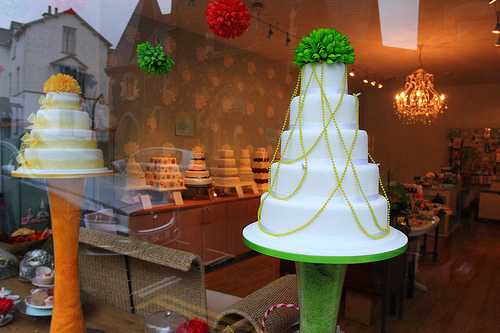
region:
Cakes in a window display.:
[5, 3, 448, 329]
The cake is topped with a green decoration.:
[261, 20, 381, 265]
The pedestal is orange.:
[10, 170, 125, 320]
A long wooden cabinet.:
[115, 195, 265, 275]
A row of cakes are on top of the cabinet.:
[105, 125, 276, 230]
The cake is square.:
[135, 150, 182, 201]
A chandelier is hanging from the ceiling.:
[380, 36, 452, 141]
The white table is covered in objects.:
[385, 160, 445, 296]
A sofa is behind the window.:
[0, 180, 305, 330]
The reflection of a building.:
[0, 6, 116, 166]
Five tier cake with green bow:
[257, 18, 425, 276]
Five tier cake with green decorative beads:
[267, 6, 403, 266]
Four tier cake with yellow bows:
[10, 53, 114, 178]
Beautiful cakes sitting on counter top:
[117, 133, 283, 214]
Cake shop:
[13, 10, 498, 332]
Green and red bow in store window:
[134, 1, 253, 79]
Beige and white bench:
[87, 226, 303, 331]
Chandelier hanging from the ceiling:
[372, 47, 464, 140]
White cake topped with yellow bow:
[7, 48, 123, 191]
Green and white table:
[232, 204, 425, 331]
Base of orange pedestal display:
[45, 179, 85, 331]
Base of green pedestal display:
[299, 261, 348, 331]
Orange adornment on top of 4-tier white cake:
[42, 69, 84, 91]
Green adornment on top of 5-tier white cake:
[293, 26, 355, 71]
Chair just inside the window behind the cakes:
[78, 226, 296, 331]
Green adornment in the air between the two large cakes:
[133, 41, 173, 74]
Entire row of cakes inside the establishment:
[115, 143, 272, 188]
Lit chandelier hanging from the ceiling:
[391, 66, 450, 125]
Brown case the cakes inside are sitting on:
[127, 192, 262, 262]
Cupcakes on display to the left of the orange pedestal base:
[26, 271, 61, 308]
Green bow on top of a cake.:
[281, 25, 359, 75]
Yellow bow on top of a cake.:
[22, 67, 84, 94]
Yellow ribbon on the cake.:
[21, 87, 103, 174]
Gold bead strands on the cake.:
[261, 64, 393, 248]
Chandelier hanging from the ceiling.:
[388, 58, 456, 127]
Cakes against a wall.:
[119, 140, 279, 188]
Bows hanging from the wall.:
[108, 1, 273, 86]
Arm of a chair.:
[215, 271, 332, 331]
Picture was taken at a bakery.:
[11, 8, 498, 330]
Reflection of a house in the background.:
[1, 11, 128, 250]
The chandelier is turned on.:
[392, 66, 445, 122]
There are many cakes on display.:
[120, 140, 272, 195]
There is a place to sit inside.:
[80, 220, 300, 325]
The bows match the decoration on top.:
[12, 65, 107, 175]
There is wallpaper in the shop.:
[175, 30, 275, 145]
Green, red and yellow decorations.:
[20, 0, 495, 90]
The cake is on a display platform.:
[11, 75, 107, 330]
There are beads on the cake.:
[247, 25, 402, 246]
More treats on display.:
[392, 169, 472, 234]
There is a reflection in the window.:
[2, 1, 109, 82]